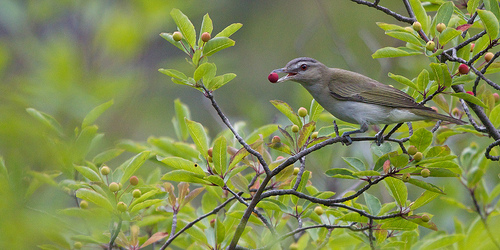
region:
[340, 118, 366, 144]
the brown leg of the bird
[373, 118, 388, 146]
the brown leg of the bird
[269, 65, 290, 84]
the brown beak of the bird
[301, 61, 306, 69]
the brown eye of the bird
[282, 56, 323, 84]
the brown head of the bird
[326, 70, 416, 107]
the brown wing of the bird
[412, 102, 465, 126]
the brown tail of the bird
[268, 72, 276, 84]
a small round red berry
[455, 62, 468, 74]
a small round red berry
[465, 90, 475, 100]
a small round red berry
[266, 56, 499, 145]
SMALL BIRD SITTING ON BRANCH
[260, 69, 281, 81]
RED BERRY IN BIRD'S MOUTH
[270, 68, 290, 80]
BEAK OF SMALL BIRD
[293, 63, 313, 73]
EYE OF SMALL BIRD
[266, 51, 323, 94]
HEAD OF SMALL BIRD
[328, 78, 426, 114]
WING FEATHERS OF SMALL BIRD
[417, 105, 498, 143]
TAIL FEATHERS OF BIRD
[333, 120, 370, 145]
FOOT OF SMALL BIRD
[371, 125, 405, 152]
FOOT OF SMALL BIRD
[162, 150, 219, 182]
GREEN LEAVES NEAR BIRD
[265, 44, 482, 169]
bird is on branch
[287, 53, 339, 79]
bird has brown head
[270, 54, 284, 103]
bird holds red berry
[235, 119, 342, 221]
branch is brown and thin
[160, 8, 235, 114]
green leaves on branches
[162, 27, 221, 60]
yellow and orange berries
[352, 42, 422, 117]
bird has brown wing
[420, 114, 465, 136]
bird has brown tail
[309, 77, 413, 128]
bird has white breast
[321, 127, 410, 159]
bird has white feet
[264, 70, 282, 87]
berry in a birds mouth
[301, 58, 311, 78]
black eye on a bird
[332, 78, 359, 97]
grey feathers on a bird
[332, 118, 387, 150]
talons on a branch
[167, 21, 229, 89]
green leaves on a branch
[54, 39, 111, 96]
blurry branch in the distance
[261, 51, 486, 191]
small bird on a branch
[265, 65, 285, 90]
red berry in a beak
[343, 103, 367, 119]
white feathers on a bird's belly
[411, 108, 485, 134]
long tail feathers on a bird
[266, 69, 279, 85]
RED BERRY IN BIRD'S BEAK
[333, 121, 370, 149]
LEG OF SMALL BIRD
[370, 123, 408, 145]
LEG OF SMALL BIRD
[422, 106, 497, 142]
TAIL OF SMALL BIRD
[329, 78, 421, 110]
WING FEATHERS OF BIRD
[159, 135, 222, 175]
PART OF GREEN LEAVES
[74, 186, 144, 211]
PART OF GREEN LEAVES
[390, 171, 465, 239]
PART OF GREEN LEAVES